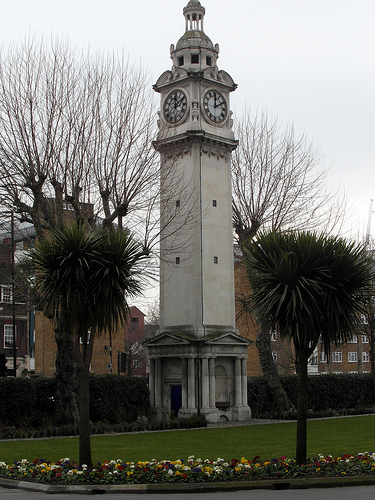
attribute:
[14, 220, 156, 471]
trees — spiky, green, these, palm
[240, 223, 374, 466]
trees — palm, green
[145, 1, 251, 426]
tower — tall, green, clock, white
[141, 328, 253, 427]
base — greek styled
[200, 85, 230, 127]
clock face — roman letter, white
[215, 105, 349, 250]
branches — dry, bare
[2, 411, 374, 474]
grass — green, lush, covering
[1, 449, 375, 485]
flowers — yellow, red, green, purple, white, colorful, these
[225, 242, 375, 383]
buildings — background, maroon, brick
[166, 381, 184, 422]
entrance — blue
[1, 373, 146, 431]
shrubs — green